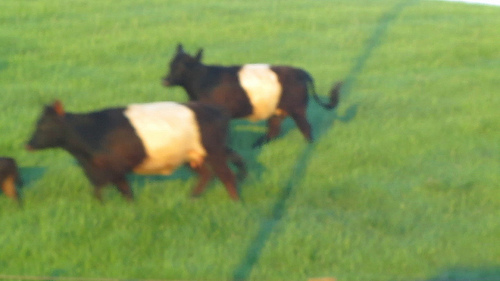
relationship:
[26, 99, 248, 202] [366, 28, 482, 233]
cow in grass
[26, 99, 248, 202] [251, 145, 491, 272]
cow on grass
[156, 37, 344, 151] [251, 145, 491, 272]
cow on grass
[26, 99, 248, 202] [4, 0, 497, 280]
cow on grass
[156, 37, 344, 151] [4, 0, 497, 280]
cow on grass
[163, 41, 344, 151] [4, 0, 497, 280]
cow on grass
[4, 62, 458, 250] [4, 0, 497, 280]
cow on grass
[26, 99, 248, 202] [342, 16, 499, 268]
cow in field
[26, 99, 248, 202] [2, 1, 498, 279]
cow in field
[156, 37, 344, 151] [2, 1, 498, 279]
cow in field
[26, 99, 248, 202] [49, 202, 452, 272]
cow in grass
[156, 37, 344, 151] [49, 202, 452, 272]
cow in grass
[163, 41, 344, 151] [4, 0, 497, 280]
cow in grass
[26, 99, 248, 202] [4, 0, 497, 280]
cow in grass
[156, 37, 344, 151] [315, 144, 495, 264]
cow in grass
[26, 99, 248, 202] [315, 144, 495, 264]
cow in grass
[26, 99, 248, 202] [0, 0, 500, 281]
cow in grass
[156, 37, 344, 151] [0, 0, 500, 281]
cow in grass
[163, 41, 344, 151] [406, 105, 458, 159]
cow in grass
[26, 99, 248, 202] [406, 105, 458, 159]
cow in grass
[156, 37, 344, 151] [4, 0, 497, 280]
cow in grass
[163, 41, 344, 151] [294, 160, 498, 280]
cow in grass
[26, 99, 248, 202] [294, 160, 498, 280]
cow in grass